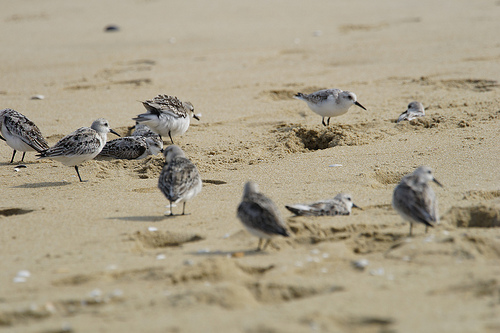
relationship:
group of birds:
[9, 84, 283, 227] [5, 82, 464, 259]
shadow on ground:
[107, 201, 164, 233] [41, 213, 119, 269]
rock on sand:
[25, 88, 51, 106] [44, 44, 254, 88]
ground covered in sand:
[41, 213, 119, 269] [44, 44, 254, 88]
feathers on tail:
[35, 148, 48, 163] [31, 151, 57, 159]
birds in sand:
[5, 82, 464, 259] [44, 44, 254, 88]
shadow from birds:
[107, 201, 164, 233] [5, 82, 464, 259]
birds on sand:
[5, 82, 464, 259] [44, 44, 254, 88]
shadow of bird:
[107, 201, 164, 233] [149, 149, 205, 212]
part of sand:
[172, 53, 228, 60] [44, 44, 254, 88]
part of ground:
[172, 53, 228, 60] [41, 213, 119, 269]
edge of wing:
[67, 150, 100, 155] [60, 134, 107, 160]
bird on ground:
[149, 149, 205, 212] [41, 213, 119, 269]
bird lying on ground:
[292, 182, 363, 232] [41, 213, 119, 269]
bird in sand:
[149, 149, 205, 212] [44, 44, 254, 88]